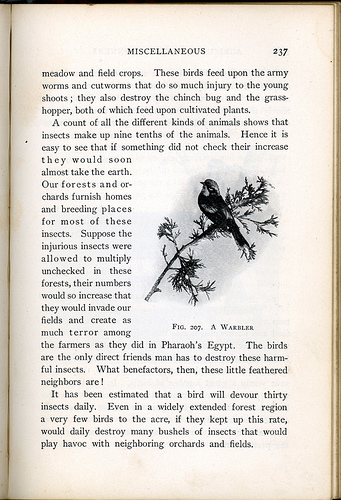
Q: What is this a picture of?
A: A page in a book.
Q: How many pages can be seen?
A: 1.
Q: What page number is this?
A: 237.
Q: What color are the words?
A: Black.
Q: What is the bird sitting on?
A: Branch.